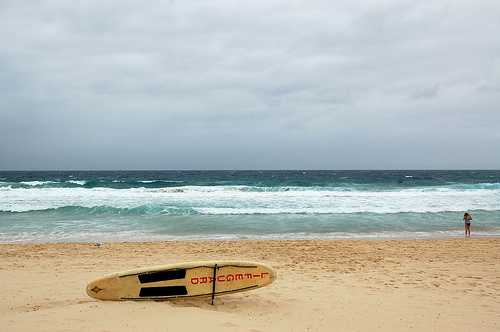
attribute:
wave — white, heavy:
[2, 176, 497, 215]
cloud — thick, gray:
[0, 2, 498, 167]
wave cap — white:
[0, 180, 499, 213]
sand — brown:
[4, 229, 495, 330]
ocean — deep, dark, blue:
[113, 153, 401, 229]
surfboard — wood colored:
[76, 258, 283, 306]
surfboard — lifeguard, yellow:
[84, 255, 286, 302]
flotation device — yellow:
[81, 250, 283, 307]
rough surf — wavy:
[7, 187, 81, 209]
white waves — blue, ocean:
[130, 188, 205, 211]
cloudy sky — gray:
[3, 1, 499, 126]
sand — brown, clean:
[3, 240, 499, 328]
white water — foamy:
[19, 179, 55, 189]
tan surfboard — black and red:
[85, 252, 286, 309]